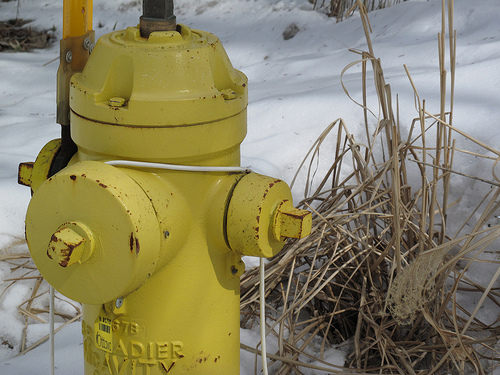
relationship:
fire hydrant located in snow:
[17, 23, 313, 374] [2, 1, 500, 374]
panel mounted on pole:
[55, 30, 95, 127] [61, 0, 92, 125]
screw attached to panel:
[83, 36, 92, 50] [55, 30, 95, 127]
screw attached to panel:
[65, 50, 74, 63] [55, 30, 95, 127]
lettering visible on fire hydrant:
[81, 319, 185, 375] [17, 23, 313, 374]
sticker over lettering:
[93, 320, 113, 354] [81, 319, 185, 375]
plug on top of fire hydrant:
[139, 0, 177, 39] [17, 23, 313, 374]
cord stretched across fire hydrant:
[49, 160, 270, 375] [17, 23, 313, 374]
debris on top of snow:
[1, 18, 59, 55] [2, 1, 500, 374]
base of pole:
[49, 124, 78, 177] [61, 0, 92, 125]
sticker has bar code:
[93, 320, 113, 354] [97, 322, 110, 334]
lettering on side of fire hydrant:
[81, 319, 185, 375] [17, 23, 313, 374]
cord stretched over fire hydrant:
[49, 160, 270, 375] [17, 23, 313, 374]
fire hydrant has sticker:
[17, 23, 313, 374] [93, 320, 113, 354]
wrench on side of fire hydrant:
[49, 0, 94, 177] [17, 23, 313, 374]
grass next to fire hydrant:
[1, 231, 24, 241] [17, 23, 313, 374]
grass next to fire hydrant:
[1, 251, 31, 260] [17, 23, 313, 374]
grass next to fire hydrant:
[2, 275, 42, 282] [17, 23, 313, 374]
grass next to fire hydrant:
[19, 273, 42, 353] [17, 23, 313, 374]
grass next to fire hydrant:
[48, 285, 57, 375] [17, 23, 313, 374]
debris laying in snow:
[1, 18, 59, 55] [2, 1, 500, 374]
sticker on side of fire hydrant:
[93, 320, 113, 354] [17, 23, 313, 374]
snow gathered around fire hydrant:
[2, 1, 500, 374] [17, 23, 313, 374]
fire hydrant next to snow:
[17, 23, 313, 374] [2, 1, 500, 374]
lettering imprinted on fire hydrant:
[81, 319, 185, 375] [17, 23, 313, 374]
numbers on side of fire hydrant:
[111, 319, 130, 336] [17, 23, 313, 374]